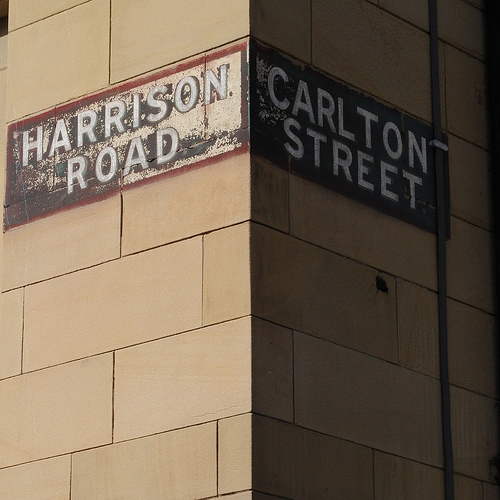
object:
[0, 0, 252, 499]
wall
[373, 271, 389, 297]
stain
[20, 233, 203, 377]
beige brick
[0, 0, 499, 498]
building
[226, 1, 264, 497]
corner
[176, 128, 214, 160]
black paint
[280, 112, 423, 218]
writing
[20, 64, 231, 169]
writing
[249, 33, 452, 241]
sign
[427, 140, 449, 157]
bracket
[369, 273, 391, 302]
hole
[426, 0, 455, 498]
long pole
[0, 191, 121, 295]
beige brick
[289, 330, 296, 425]
gap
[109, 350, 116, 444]
gap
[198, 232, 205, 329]
gap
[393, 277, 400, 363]
gap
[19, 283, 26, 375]
gap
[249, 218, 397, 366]
brick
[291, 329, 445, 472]
brick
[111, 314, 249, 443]
brick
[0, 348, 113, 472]
brick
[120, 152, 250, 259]
brick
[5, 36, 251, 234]
sign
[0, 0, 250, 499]
sun reflected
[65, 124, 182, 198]
word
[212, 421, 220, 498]
crack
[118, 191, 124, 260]
gap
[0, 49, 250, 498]
light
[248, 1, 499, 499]
shade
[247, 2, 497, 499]
wall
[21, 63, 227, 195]
harrison road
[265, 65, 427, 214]
carlton street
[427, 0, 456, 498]
cord